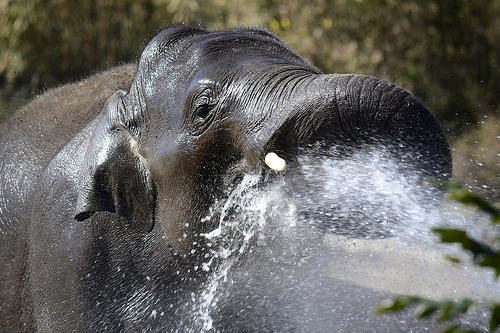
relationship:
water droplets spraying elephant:
[326, 135, 466, 245] [0, 25, 472, 333]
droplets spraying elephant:
[262, 241, 342, 318] [5, 24, 483, 253]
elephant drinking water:
[0, 25, 472, 333] [59, 78, 499, 331]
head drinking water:
[57, 20, 453, 219] [310, 165, 396, 253]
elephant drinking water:
[0, 25, 472, 333] [237, 201, 440, 331]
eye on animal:
[192, 103, 213, 118] [1, 26, 453, 331]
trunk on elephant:
[298, 66, 456, 259] [13, 30, 473, 331]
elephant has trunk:
[0, 25, 472, 333] [239, 70, 455, 243]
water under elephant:
[59, 78, 499, 331] [0, 25, 472, 333]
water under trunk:
[59, 78, 499, 331] [265, 64, 449, 194]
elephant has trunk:
[0, 25, 472, 333] [265, 64, 449, 194]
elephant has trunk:
[0, 25, 472, 333] [266, 70, 452, 249]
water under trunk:
[59, 78, 499, 331] [247, 63, 446, 193]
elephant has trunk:
[0, 25, 472, 333] [247, 63, 446, 193]